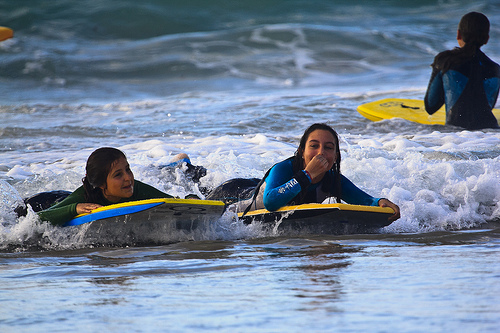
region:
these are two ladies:
[34, 100, 375, 240]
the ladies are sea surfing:
[57, 120, 386, 247]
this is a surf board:
[114, 195, 208, 226]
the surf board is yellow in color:
[149, 192, 226, 224]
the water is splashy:
[181, 218, 222, 235]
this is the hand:
[284, 159, 329, 196]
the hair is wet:
[84, 154, 104, 182]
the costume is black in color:
[453, 55, 495, 114]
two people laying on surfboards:
[20, 115, 388, 269]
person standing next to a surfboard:
[354, 3, 499, 144]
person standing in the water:
[422, 6, 497, 131]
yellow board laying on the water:
[348, 92, 498, 134]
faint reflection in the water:
[271, 231, 362, 317]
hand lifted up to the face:
[297, 146, 342, 181]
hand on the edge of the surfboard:
[370, 193, 403, 219]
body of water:
[2, 2, 498, 332]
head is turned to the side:
[77, 145, 137, 195]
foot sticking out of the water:
[157, 143, 192, 177]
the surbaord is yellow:
[378, 94, 430, 129]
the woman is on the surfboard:
[206, 155, 383, 209]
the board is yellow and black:
[281, 187, 396, 228]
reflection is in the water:
[313, 237, 356, 301]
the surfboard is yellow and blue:
[92, 192, 224, 232]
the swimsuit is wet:
[179, 157, 366, 205]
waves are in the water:
[87, 22, 380, 99]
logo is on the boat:
[386, 94, 418, 114]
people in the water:
[13, 9, 493, 300]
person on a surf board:
[11, 151, 225, 237]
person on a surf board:
[168, 120, 392, 229]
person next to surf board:
[358, 11, 498, 138]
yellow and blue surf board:
[100, 190, 230, 238]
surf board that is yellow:
[238, 187, 412, 234]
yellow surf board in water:
[356, 88, 470, 125]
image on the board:
[373, 97, 422, 116]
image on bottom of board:
[162, 203, 206, 220]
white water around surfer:
[12, 118, 492, 231]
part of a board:
[177, 193, 204, 228]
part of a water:
[216, 274, 249, 319]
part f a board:
[144, 171, 202, 246]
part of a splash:
[321, 225, 337, 241]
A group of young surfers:
[0, 0, 499, 331]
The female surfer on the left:
[33, 149, 228, 235]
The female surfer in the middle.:
[234, 124, 399, 231]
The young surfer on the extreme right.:
[359, 11, 499, 132]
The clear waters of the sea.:
[0, 0, 499, 331]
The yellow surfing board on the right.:
[356, 97, 498, 126]